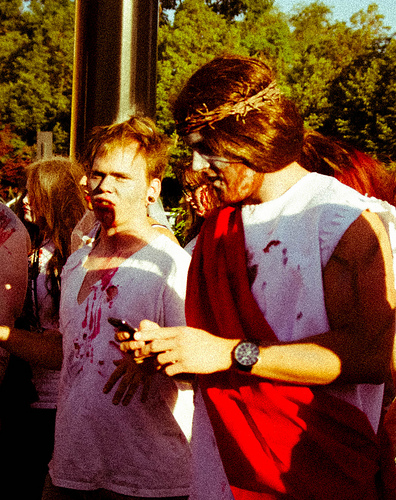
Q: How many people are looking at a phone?
A: One.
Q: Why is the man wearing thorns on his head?
A: Costume.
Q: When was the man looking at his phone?
A: Daytime.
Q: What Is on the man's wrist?
A: A watch.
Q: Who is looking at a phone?
A: A man.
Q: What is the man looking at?
A: A phone.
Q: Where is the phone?
A: The man's hand.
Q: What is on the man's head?
A: Thorns.